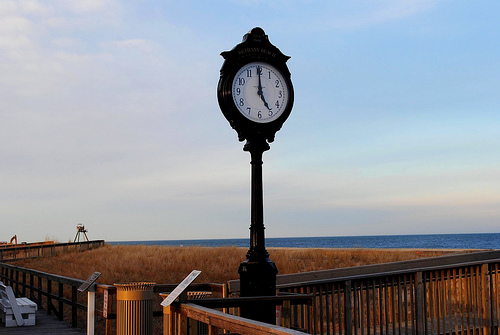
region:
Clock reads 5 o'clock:
[218, 25, 295, 322]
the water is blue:
[108, 231, 499, 253]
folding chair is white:
[0, 280, 37, 326]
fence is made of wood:
[1, 237, 498, 329]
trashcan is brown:
[113, 280, 153, 330]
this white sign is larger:
[158, 268, 200, 308]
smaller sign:
[83, 270, 107, 295]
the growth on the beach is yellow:
[23, 244, 478, 288]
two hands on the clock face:
[255, 65, 274, 114]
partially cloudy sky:
[3, 8, 497, 231]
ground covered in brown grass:
[114, 246, 184, 278]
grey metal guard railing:
[340, 262, 497, 332]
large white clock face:
[232, 58, 294, 123]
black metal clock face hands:
[252, 63, 275, 115]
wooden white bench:
[0, 283, 42, 325]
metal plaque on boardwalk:
[73, 265, 107, 299]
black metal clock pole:
[236, 129, 283, 293]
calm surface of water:
[353, 231, 498, 245]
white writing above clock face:
[232, 37, 286, 60]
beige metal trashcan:
[110, 275, 157, 334]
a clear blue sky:
[345, 54, 477, 179]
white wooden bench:
[1, 287, 41, 328]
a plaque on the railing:
[157, 269, 201, 308]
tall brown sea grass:
[131, 244, 204, 271]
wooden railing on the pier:
[340, 270, 482, 314]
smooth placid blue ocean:
[280, 231, 495, 248]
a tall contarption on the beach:
[72, 222, 99, 247]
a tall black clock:
[204, 20, 317, 286]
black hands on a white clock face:
[251, 69, 271, 114]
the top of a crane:
[8, 231, 20, 245]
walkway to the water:
[163, 248, 497, 323]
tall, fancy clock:
[216, 28, 294, 298]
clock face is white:
[232, 61, 288, 124]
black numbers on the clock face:
[231, 63, 288, 126]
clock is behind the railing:
[215, 27, 298, 325]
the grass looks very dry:
[5, 243, 496, 331]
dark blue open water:
[99, 234, 498, 251]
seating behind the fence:
[1, 280, 38, 326]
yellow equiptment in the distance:
[1, 232, 27, 247]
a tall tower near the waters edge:
[72, 222, 92, 241]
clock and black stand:
[212, 18, 312, 324]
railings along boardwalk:
[6, 228, 491, 328]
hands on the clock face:
[251, 64, 273, 115]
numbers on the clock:
[225, 62, 292, 127]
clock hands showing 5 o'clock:
[250, 62, 284, 122]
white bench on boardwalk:
[0, 281, 37, 330]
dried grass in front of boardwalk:
[45, 244, 493, 334]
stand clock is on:
[238, 141, 285, 329]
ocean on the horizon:
[110, 231, 493, 256]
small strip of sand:
[190, 244, 480, 255]